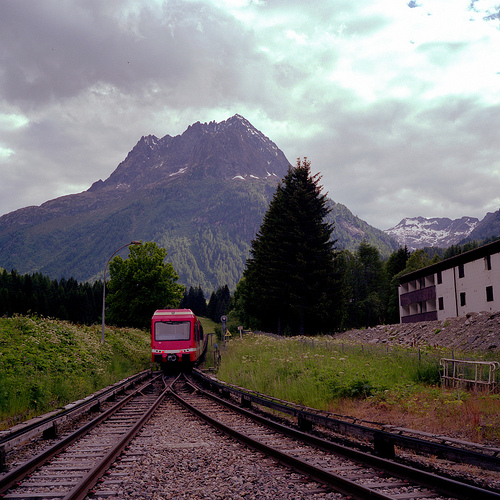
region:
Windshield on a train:
[154, 319, 191, 340]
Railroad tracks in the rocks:
[17, 406, 425, 493]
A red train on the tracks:
[146, 304, 208, 363]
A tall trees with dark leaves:
[247, 158, 342, 328]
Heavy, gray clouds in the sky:
[4, 4, 490, 221]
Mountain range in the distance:
[9, 110, 496, 274]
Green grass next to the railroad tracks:
[1, 325, 143, 430]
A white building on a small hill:
[393, 247, 498, 323]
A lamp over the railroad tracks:
[99, 238, 144, 351]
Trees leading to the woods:
[6, 250, 152, 325]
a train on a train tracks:
[147, 293, 205, 390]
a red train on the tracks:
[169, 251, 246, 401]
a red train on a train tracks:
[103, 248, 265, 451]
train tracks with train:
[153, 327, 246, 482]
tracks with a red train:
[128, 277, 243, 415]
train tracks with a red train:
[101, 298, 261, 435]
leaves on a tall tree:
[261, 175, 339, 300]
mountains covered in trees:
[35, 51, 324, 289]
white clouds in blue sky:
[335, 156, 376, 186]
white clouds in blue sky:
[343, 115, 408, 170]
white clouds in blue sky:
[324, 62, 395, 115]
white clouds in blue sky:
[58, 70, 130, 87]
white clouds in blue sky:
[77, 21, 122, 76]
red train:
[127, 301, 202, 359]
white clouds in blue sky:
[402, 36, 443, 66]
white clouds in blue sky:
[342, 78, 414, 138]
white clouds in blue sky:
[412, 62, 493, 127]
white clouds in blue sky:
[234, 35, 294, 79]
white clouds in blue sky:
[75, 32, 146, 74]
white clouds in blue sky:
[31, 16, 98, 54]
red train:
[148, 289, 213, 389]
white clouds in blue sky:
[370, 119, 401, 130]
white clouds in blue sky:
[355, 45, 459, 147]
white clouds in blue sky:
[411, 142, 485, 186]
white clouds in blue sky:
[280, 56, 324, 104]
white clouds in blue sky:
[110, 13, 208, 61]